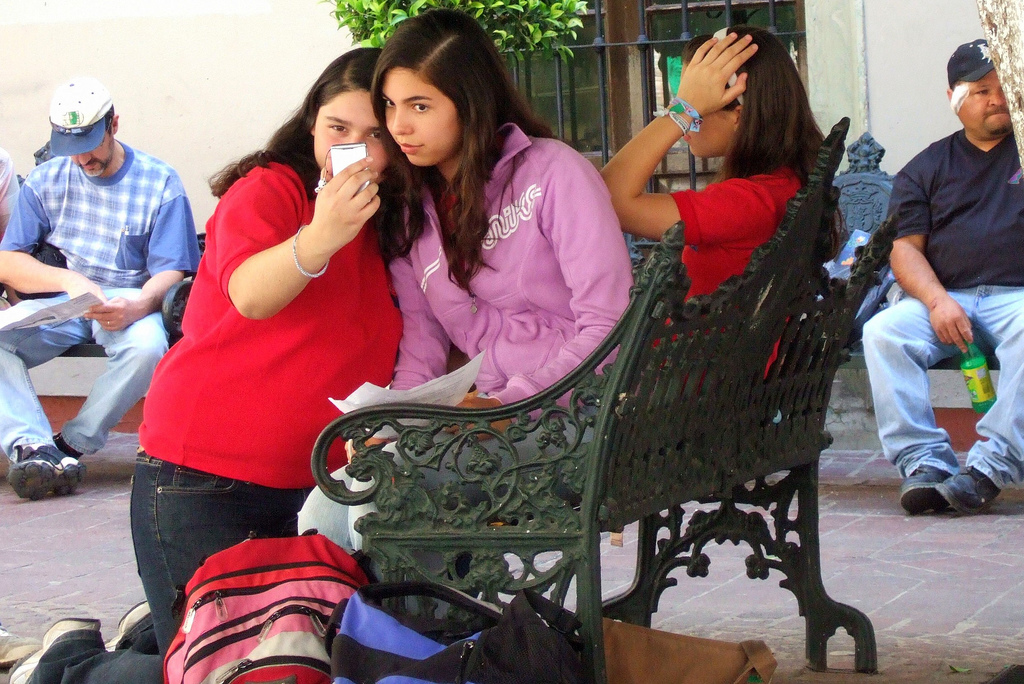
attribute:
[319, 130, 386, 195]
cell phone — rectangular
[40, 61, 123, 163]
hat — blue, white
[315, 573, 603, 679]
bag — blue, black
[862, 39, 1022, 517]
person — sitting down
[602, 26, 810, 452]
person — sitting down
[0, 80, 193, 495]
person — sitting down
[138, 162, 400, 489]
shirt — red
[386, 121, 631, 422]
shirt — purple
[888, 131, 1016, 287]
shirt — blue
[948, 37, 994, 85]
hat — blue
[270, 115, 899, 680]
bench — metal